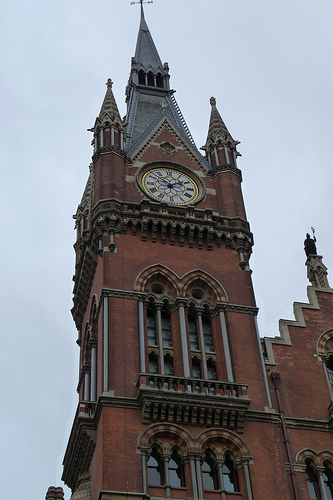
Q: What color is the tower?
A: Reddish.